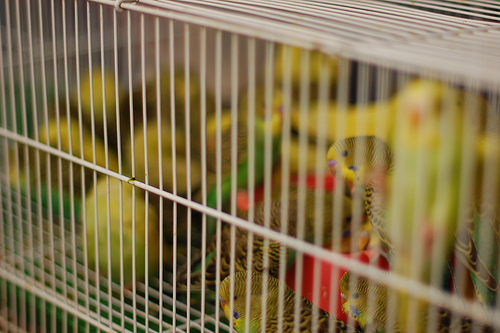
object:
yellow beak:
[324, 133, 344, 180]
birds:
[26, 100, 103, 181]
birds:
[142, 50, 199, 120]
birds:
[71, 60, 127, 123]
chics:
[203, 132, 493, 328]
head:
[325, 126, 395, 188]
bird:
[171, 188, 367, 288]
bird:
[78, 175, 175, 279]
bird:
[124, 117, 210, 192]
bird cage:
[19, 12, 498, 326]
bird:
[324, 135, 499, 292]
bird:
[338, 262, 453, 330]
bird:
[215, 270, 357, 331]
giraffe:
[320, 88, 457, 220]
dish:
[262, 173, 402, 314]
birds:
[260, 36, 334, 90]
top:
[115, 0, 498, 91]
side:
[5, 0, 499, 330]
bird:
[290, 78, 444, 164]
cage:
[1, 2, 499, 331]